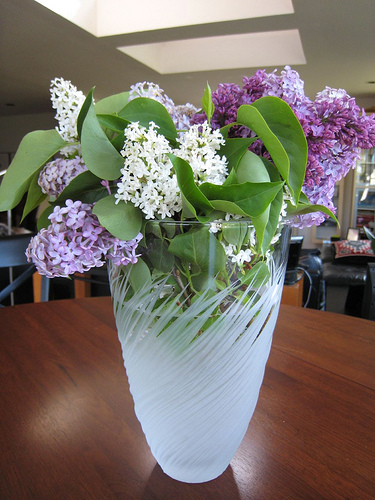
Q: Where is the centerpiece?
A: On the table.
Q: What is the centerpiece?
A: A vase of flowers.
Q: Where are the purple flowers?
A: In the vase.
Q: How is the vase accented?
A: Frosted.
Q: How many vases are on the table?
A: One.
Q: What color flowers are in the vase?
A: White and purple.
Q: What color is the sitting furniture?
A: Black.